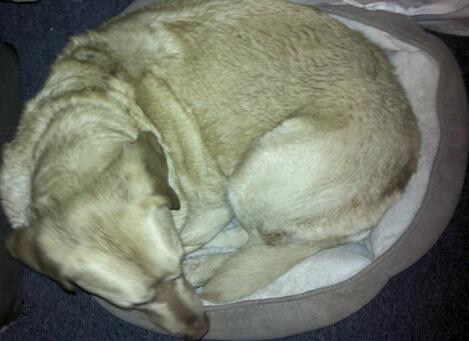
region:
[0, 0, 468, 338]
The dog is sleeping.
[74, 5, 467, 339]
The dog is sleeping in a bed.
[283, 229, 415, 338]
The bed is tan.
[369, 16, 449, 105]
The bed is white.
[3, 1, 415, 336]
The dog is tan.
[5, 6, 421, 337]
The dog is short haired.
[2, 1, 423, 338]
The dog is curled up.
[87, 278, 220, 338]
The dog's nose hangs over the bed's edge.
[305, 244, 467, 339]
The bed is on a carpet.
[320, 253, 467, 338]
The carpet is dark blue.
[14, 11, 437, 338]
a dog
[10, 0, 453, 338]
a sleeping dog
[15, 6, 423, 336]
the dog is sleeping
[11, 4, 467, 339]
the dog is on a bed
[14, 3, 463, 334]
the dog sleeps on a tan and white dog bed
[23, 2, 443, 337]
the dog is curled up in a ball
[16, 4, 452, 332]
the dog is a light tan color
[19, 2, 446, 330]
the dog lays curled up on a plush dog bed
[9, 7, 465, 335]
the dog bed is on the floor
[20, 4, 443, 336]
a large dog sleeping on a cushion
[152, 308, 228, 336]
A brown dog nose.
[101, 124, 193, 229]
An ear of a dog.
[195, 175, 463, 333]
gray and white dog bed.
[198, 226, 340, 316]
Off white tail of a dog.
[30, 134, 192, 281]
Top of a dogs head.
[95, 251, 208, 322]
Two eye lids of a dog.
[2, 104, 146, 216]
Hairy nape of a dogs neck.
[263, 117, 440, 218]
Hairy but of a dog.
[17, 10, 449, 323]
Dog sleeping in doggy bed.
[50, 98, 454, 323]
Dog curled up sleeping.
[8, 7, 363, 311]
this is a dog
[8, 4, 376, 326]
the dog is pale brown in color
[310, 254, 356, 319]
the dog is sleeping on a mat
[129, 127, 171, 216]
this is the ear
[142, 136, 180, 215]
the ear is folded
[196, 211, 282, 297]
the legs are folded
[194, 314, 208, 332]
the dog is black in color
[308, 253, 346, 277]
the mat is white in color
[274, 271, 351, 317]
the mat is round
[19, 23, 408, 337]
off white dog laying down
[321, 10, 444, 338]
gray and white dog bed cushion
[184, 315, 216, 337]
brown dog nose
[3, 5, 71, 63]
Blue carpet under dog cushion in top left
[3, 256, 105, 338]
Dog ear and blue carpet in bottom left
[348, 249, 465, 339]
Dog cushion and blue carpet in bottom right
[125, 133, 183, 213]
Dog ear on top,right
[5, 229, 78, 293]
dogs ear on bottom left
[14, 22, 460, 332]
White dog curled up sleeping on its bed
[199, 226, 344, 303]
Dogs tail tucked under